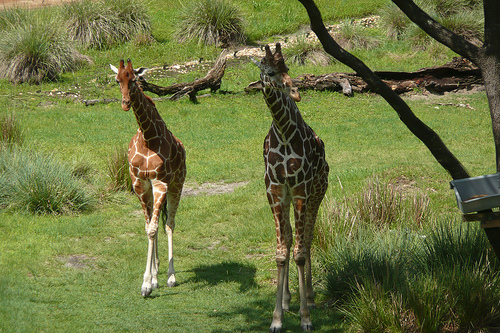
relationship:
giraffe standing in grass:
[108, 60, 188, 290] [2, 204, 276, 331]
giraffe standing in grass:
[243, 42, 330, 329] [2, 204, 276, 331]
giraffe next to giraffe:
[108, 60, 188, 290] [243, 42, 330, 329]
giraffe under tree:
[243, 42, 330, 329] [300, 0, 499, 256]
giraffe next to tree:
[243, 42, 330, 329] [300, 0, 499, 256]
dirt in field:
[183, 177, 251, 197] [2, 76, 495, 327]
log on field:
[133, 51, 230, 102] [2, 76, 495, 327]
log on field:
[288, 56, 482, 98] [2, 76, 495, 327]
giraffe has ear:
[108, 60, 188, 290] [109, 62, 119, 75]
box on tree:
[450, 169, 500, 210] [300, 0, 499, 256]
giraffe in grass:
[108, 60, 188, 290] [2, 204, 276, 331]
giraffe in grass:
[243, 42, 330, 329] [2, 204, 276, 331]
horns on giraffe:
[117, 58, 133, 69] [108, 60, 188, 290]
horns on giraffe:
[263, 40, 285, 62] [243, 42, 330, 329]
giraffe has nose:
[108, 60, 188, 290] [120, 96, 132, 107]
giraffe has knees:
[108, 60, 188, 290] [145, 223, 159, 242]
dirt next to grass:
[183, 177, 251, 197] [2, 204, 276, 331]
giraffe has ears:
[108, 60, 188, 290] [109, 65, 150, 78]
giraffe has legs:
[108, 60, 188, 290] [140, 226, 178, 296]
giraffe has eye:
[243, 42, 330, 329] [266, 69, 276, 77]